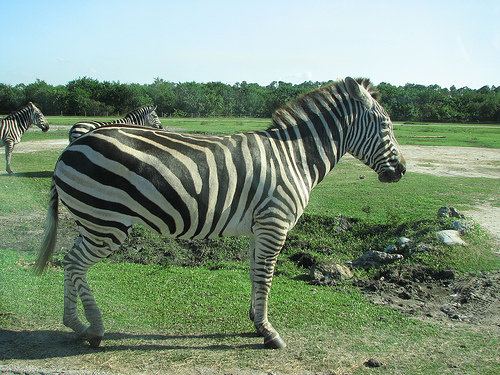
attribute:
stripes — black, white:
[135, 148, 278, 220]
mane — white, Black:
[267, 77, 377, 127]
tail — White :
[31, 180, 59, 280]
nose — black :
[382, 157, 406, 190]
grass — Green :
[341, 183, 386, 217]